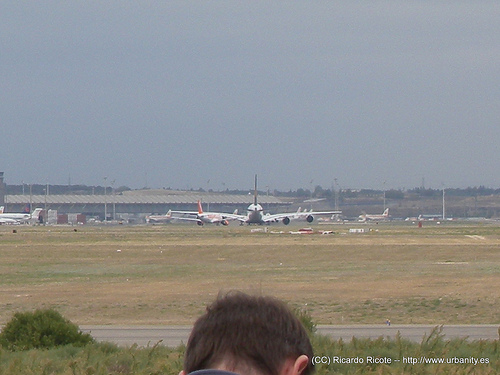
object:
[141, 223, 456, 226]
runway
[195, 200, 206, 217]
tail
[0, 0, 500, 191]
blue sky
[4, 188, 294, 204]
roof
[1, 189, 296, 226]
building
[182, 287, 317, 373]
hair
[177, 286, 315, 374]
head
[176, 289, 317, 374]
man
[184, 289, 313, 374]
hair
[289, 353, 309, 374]
ear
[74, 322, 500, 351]
road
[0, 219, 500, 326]
field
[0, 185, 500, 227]
air port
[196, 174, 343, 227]
plane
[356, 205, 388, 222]
plane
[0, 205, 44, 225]
plane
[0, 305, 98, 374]
trees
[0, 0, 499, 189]
clouds